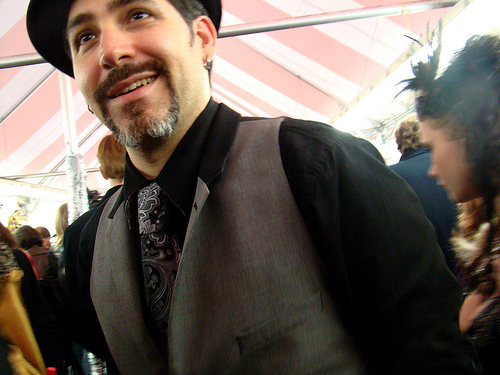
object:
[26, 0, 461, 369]
man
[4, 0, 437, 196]
tent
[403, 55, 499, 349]
woman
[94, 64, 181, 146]
goatee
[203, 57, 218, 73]
earring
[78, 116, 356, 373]
vest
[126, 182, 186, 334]
tie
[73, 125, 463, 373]
shirt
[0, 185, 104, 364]
crowd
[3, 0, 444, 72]
pole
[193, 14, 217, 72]
ear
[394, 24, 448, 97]
feathers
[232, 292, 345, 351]
pocket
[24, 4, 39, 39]
rim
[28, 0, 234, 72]
hat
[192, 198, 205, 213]
button hole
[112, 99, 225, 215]
collar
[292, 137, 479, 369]
sleeve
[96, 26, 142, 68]
nose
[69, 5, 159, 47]
eyes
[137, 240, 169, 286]
design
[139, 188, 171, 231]
knot